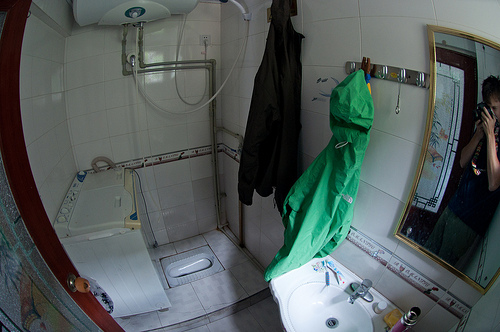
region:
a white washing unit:
[53, 166, 169, 316]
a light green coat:
[266, 70, 376, 280]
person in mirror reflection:
[419, 75, 499, 265]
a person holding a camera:
[427, 73, 499, 264]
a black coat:
[238, 12, 306, 213]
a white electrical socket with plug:
[198, 31, 209, 46]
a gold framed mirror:
[394, 23, 499, 293]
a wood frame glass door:
[1, 10, 125, 330]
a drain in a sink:
[324, 311, 338, 328]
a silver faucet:
[347, 278, 374, 304]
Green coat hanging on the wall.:
[256, 65, 377, 280]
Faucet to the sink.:
[347, 284, 366, 306]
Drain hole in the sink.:
[322, 318, 344, 326]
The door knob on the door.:
[65, 271, 91, 291]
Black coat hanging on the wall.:
[241, 0, 308, 216]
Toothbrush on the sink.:
[320, 256, 333, 284]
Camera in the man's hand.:
[472, 102, 487, 127]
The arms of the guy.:
[460, 106, 498, 196]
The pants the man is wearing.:
[434, 203, 467, 271]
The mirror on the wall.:
[396, 50, 498, 291]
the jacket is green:
[341, 93, 367, 116]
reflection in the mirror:
[417, 85, 482, 254]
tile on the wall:
[63, 90, 141, 132]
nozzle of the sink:
[332, 279, 367, 308]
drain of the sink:
[322, 312, 346, 329]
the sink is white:
[298, 299, 311, 308]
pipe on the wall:
[112, 26, 217, 79]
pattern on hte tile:
[133, 153, 215, 162]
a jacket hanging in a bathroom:
[300, 61, 375, 266]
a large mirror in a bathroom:
[424, 28, 491, 265]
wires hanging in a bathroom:
[107, 9, 247, 109]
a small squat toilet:
[151, 232, 238, 292]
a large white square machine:
[61, 155, 172, 296]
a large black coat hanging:
[238, 21, 313, 199]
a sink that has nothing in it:
[262, 243, 390, 330]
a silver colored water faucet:
[335, 271, 376, 311]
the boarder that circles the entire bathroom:
[138, 138, 216, 175]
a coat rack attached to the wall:
[351, 51, 441, 106]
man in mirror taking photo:
[386, 23, 496, 289]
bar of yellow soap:
[380, 306, 400, 326]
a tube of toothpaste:
[320, 258, 347, 286]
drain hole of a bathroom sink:
[323, 316, 343, 326]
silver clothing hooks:
[343, 61, 425, 87]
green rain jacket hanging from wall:
[260, 68, 371, 283]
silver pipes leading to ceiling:
[112, 24, 228, 234]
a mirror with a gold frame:
[382, 21, 497, 291]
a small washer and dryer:
[59, 171, 174, 328]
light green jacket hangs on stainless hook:
[263, 68, 368, 278]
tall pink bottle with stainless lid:
[385, 306, 416, 329]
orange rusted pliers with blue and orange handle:
[356, 55, 371, 96]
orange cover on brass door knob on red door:
[75, 276, 88, 291]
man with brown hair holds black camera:
[422, 74, 497, 272]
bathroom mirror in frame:
[395, 23, 498, 291]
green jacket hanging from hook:
[266, 61, 429, 281]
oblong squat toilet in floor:
[159, 242, 223, 286]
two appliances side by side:
[55, 164, 170, 325]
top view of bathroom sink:
[270, 257, 402, 329]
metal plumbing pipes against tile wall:
[119, 25, 223, 225]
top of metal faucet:
[347, 277, 373, 303]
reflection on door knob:
[68, 274, 90, 295]